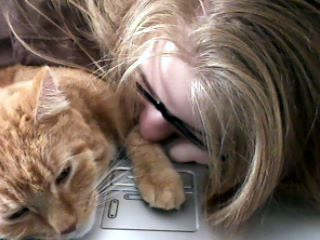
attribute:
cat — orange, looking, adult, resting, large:
[4, 64, 189, 240]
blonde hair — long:
[9, 0, 313, 237]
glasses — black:
[128, 76, 217, 152]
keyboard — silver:
[28, 159, 211, 237]